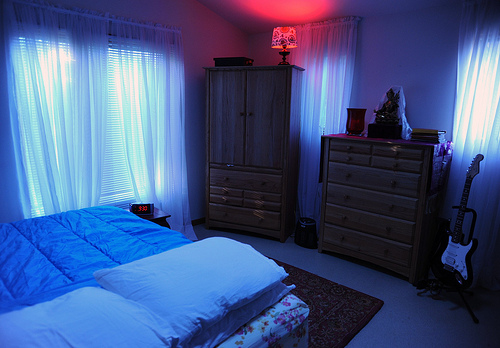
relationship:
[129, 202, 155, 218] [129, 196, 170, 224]
alarm clock on table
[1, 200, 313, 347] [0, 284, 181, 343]
bed has pillow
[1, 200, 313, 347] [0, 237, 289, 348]
bed has pillow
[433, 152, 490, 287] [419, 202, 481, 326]
guitar on stand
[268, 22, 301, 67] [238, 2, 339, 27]
lamp emitting light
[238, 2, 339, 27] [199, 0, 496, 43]
light on ceiling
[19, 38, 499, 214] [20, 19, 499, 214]
light coming from outside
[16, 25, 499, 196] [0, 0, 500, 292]
blinds under blinds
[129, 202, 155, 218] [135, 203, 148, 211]
alarm clock says 9:30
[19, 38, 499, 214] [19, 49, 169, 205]
light coming through window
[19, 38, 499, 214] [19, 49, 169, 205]
light through window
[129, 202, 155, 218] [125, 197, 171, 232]
alarm clock on stool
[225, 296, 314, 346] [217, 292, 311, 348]
flowers on flowers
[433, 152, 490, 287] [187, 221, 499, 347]
guitar on ground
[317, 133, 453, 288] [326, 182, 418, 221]
cabinets with drawer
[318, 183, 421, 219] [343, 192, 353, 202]
drawer has handle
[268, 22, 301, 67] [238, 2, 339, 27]
lamp with light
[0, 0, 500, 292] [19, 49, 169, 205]
blinds over window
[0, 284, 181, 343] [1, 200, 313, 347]
pillow over bed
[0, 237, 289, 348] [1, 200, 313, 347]
pillow over bed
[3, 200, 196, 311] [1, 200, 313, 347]
comforter on bed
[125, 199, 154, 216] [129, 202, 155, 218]
alarm clock on alarm clock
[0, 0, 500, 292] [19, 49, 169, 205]
blinds on window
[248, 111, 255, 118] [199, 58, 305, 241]
knob on cabinet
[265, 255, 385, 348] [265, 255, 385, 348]
carpet has carpet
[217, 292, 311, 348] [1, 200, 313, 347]
flowers on bed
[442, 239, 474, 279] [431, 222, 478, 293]
white on guitar face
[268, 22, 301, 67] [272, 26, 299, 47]
lamp with shade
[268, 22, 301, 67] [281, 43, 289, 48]
lamp with lightbulb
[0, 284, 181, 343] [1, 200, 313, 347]
pillow on bed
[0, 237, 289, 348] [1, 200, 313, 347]
pillow on bed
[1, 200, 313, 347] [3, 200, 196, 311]
bed with comforter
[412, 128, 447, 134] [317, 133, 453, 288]
book on cabinets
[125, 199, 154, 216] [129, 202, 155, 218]
alarm clock with alarm clock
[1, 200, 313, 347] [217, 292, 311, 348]
bed with flowers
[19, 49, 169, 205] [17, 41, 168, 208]
window with blinds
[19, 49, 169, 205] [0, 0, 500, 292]
window with blinds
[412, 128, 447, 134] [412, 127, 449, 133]
book with book